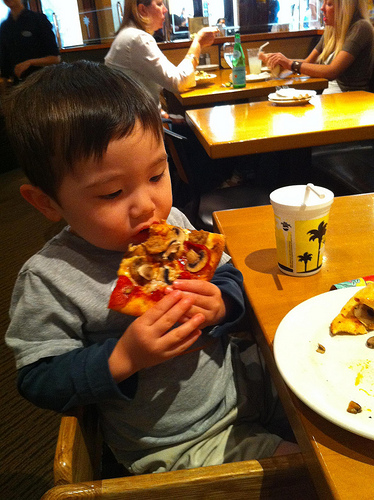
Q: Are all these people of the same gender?
A: No, they are both male and female.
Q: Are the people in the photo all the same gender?
A: No, they are both male and female.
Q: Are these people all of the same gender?
A: No, they are both male and female.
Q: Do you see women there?
A: Yes, there is a woman.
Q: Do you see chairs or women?
A: Yes, there is a woman.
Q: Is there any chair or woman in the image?
A: Yes, there is a woman.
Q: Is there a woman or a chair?
A: Yes, there is a woman.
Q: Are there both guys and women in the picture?
A: No, there is a woman but no guys.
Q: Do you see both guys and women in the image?
A: No, there is a woman but no guys.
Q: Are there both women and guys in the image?
A: No, there is a woman but no guys.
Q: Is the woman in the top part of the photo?
A: Yes, the woman is in the top of the image.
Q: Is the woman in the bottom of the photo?
A: No, the woman is in the top of the image.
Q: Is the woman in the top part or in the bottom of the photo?
A: The woman is in the top of the image.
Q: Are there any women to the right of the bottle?
A: Yes, there is a woman to the right of the bottle.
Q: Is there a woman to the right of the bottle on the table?
A: Yes, there is a woman to the right of the bottle.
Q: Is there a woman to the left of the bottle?
A: No, the woman is to the right of the bottle.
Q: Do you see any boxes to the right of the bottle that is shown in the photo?
A: No, there is a woman to the right of the bottle.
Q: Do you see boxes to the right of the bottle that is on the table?
A: No, there is a woman to the right of the bottle.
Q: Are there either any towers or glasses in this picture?
A: No, there are no glasses or towers.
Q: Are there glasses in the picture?
A: No, there are no glasses.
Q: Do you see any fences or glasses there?
A: No, there are no glasses or fences.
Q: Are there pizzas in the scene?
A: Yes, there is a pizza.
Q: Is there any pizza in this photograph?
A: Yes, there is a pizza.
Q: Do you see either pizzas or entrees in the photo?
A: Yes, there is a pizza.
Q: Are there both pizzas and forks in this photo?
A: No, there is a pizza but no forks.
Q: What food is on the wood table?
A: The food is a pizza.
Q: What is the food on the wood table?
A: The food is a pizza.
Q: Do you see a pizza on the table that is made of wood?
A: Yes, there is a pizza on the table.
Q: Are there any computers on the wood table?
A: No, there is a pizza on the table.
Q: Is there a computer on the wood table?
A: No, there is a pizza on the table.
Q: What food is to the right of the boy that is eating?
A: The food is a pizza.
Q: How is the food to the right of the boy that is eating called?
A: The food is a pizza.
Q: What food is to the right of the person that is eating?
A: The food is a pizza.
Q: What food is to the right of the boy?
A: The food is a pizza.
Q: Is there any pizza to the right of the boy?
A: Yes, there is a pizza to the right of the boy.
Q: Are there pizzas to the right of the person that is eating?
A: Yes, there is a pizza to the right of the boy.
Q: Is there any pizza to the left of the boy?
A: No, the pizza is to the right of the boy.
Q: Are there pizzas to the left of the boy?
A: No, the pizza is to the right of the boy.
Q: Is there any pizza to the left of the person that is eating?
A: No, the pizza is to the right of the boy.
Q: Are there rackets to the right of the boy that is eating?
A: No, there is a pizza to the right of the boy.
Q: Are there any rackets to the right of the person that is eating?
A: No, there is a pizza to the right of the boy.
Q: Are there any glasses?
A: No, there are no glasses.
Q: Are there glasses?
A: No, there are no glasses.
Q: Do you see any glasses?
A: No, there are no glasses.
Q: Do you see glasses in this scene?
A: No, there are no glasses.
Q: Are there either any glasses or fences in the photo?
A: No, there are no glasses or fences.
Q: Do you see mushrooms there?
A: Yes, there are mushrooms.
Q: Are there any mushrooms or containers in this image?
A: Yes, there are mushrooms.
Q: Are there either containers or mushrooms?
A: Yes, there are mushrooms.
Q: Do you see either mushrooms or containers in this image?
A: Yes, there are mushrooms.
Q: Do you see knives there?
A: No, there are no knives.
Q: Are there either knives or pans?
A: No, there are no knives or pans.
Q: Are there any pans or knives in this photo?
A: No, there are no knives or pans.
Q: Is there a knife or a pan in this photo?
A: No, there are no knives or pans.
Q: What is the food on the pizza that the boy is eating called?
A: The food is mushrooms.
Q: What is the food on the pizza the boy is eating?
A: The food is mushrooms.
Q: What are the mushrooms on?
A: The mushrooms are on the pizza.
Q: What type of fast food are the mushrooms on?
A: The mushrooms are on the pizza.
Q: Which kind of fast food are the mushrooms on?
A: The mushrooms are on the pizza.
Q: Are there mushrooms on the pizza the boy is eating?
A: Yes, there are mushrooms on the pizza.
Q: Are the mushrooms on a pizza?
A: Yes, the mushrooms are on a pizza.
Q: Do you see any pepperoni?
A: Yes, there is pepperoni.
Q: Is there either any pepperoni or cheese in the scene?
A: Yes, there is pepperoni.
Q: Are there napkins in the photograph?
A: No, there are no napkins.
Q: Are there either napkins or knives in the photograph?
A: No, there are no napkins or knives.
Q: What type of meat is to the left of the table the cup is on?
A: The meat is pepperoni.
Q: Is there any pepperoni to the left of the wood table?
A: Yes, there is pepperoni to the left of the table.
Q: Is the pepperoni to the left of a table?
A: Yes, the pepperoni is to the left of a table.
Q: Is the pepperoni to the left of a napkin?
A: No, the pepperoni is to the left of a table.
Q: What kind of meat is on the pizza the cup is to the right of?
A: The meat is pepperoni.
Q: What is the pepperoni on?
A: The pepperoni is on the pizza.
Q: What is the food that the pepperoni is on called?
A: The food is a pizza.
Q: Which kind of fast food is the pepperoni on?
A: The pepperoni is on the pizza.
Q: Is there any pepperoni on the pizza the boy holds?
A: Yes, there is pepperoni on the pizza.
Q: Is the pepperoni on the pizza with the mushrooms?
A: Yes, the pepperoni is on the pizza.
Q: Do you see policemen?
A: No, there are no policemen.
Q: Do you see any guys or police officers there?
A: No, there are no police officers or guys.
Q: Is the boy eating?
A: Yes, the boy is eating.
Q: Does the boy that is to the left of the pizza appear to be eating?
A: Yes, the boy is eating.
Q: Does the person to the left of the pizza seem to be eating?
A: Yes, the boy is eating.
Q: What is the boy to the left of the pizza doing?
A: The boy is eating.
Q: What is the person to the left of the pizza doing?
A: The boy is eating.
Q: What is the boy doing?
A: The boy is eating.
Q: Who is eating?
A: The boy is eating.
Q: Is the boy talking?
A: No, the boy is eating.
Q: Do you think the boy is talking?
A: No, the boy is eating.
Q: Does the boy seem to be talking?
A: No, the boy is eating.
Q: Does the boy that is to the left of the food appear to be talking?
A: No, the boy is eating.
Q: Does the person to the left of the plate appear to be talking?
A: No, the boy is eating.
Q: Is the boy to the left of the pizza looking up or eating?
A: The boy is eating.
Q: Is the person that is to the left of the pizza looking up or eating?
A: The boy is eating.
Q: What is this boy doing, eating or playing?
A: The boy is eating.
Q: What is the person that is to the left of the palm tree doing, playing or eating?
A: The boy is eating.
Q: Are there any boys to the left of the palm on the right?
A: Yes, there is a boy to the left of the palm tree.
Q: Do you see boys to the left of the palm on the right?
A: Yes, there is a boy to the left of the palm tree.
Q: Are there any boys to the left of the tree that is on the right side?
A: Yes, there is a boy to the left of the palm tree.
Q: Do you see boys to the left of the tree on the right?
A: Yes, there is a boy to the left of the palm tree.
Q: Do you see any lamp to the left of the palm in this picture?
A: No, there is a boy to the left of the palm.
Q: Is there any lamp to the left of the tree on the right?
A: No, there is a boy to the left of the palm.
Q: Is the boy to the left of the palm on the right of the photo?
A: Yes, the boy is to the left of the palm.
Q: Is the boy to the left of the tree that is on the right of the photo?
A: Yes, the boy is to the left of the palm.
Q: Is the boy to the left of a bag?
A: No, the boy is to the left of the palm.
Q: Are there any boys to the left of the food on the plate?
A: Yes, there is a boy to the left of the food.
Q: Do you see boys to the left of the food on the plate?
A: Yes, there is a boy to the left of the food.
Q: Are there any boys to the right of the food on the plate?
A: No, the boy is to the left of the food.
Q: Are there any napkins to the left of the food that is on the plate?
A: No, there is a boy to the left of the food.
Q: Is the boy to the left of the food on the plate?
A: Yes, the boy is to the left of the food.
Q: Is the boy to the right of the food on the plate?
A: No, the boy is to the left of the food.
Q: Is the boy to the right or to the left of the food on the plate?
A: The boy is to the left of the food.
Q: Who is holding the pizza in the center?
A: The boy is holding the pizza.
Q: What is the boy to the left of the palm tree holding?
A: The boy is holding the pizza.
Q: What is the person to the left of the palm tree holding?
A: The boy is holding the pizza.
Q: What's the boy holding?
A: The boy is holding the pizza.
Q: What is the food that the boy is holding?
A: The food is a pizza.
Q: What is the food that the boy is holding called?
A: The food is a pizza.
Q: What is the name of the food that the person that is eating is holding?
A: The food is a pizza.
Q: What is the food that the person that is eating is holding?
A: The food is a pizza.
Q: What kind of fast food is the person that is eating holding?
A: The boy is holding the pizza.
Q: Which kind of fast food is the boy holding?
A: The boy is holding the pizza.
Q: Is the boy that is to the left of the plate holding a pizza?
A: Yes, the boy is holding a pizza.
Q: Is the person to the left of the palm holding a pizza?
A: Yes, the boy is holding a pizza.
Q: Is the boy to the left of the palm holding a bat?
A: No, the boy is holding a pizza.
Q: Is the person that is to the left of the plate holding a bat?
A: No, the boy is holding a pizza.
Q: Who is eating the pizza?
A: The boy is eating the pizza.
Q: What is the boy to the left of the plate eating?
A: The boy is eating a pizza.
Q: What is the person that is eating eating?
A: The boy is eating a pizza.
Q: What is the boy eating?
A: The boy is eating a pizza.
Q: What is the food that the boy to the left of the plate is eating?
A: The food is a pizza.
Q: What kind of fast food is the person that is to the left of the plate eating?
A: The boy is eating a pizza.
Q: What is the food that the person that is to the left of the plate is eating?
A: The food is a pizza.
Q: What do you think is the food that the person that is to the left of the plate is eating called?
A: The food is a pizza.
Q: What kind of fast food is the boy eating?
A: The boy is eating a pizza.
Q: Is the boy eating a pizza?
A: Yes, the boy is eating a pizza.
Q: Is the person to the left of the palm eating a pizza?
A: Yes, the boy is eating a pizza.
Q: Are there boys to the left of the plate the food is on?
A: Yes, there is a boy to the left of the plate.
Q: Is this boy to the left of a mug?
A: No, the boy is to the left of the plate.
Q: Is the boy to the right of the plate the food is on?
A: No, the boy is to the left of the plate.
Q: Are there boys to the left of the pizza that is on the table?
A: Yes, there is a boy to the left of the pizza.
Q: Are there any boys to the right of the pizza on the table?
A: No, the boy is to the left of the pizza.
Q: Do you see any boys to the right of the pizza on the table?
A: No, the boy is to the left of the pizza.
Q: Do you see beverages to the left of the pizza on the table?
A: No, there is a boy to the left of the pizza.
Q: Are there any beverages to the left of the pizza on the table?
A: No, there is a boy to the left of the pizza.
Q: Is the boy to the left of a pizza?
A: Yes, the boy is to the left of a pizza.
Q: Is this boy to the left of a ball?
A: No, the boy is to the left of a pizza.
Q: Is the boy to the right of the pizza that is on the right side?
A: No, the boy is to the left of the pizza.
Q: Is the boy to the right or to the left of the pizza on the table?
A: The boy is to the left of the pizza.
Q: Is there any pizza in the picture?
A: Yes, there is a pizza.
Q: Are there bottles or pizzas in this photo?
A: Yes, there is a pizza.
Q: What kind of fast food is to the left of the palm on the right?
A: The food is a pizza.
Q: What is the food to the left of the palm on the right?
A: The food is a pizza.